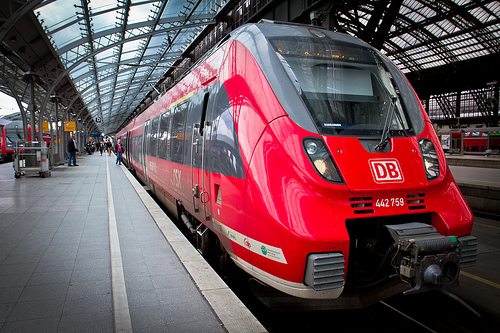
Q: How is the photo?
A: Clear.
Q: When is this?
A: Daytime.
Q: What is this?
A: Train.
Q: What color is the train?
A: Red.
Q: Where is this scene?
A: Train station.